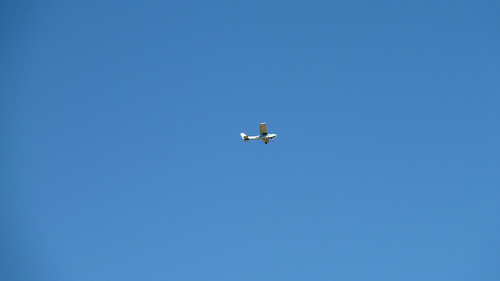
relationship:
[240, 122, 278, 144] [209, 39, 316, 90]
airplane flying under blue sky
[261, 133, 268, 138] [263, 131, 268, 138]
rectangular shape of window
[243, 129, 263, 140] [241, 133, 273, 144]
side of plane reflecting light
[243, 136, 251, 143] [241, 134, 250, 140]
dark panel on tail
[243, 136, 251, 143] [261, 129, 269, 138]
dark window under wing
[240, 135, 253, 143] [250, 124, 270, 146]
black dog against wing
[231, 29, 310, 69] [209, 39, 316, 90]
part of sky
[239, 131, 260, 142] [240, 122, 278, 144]
part of airplane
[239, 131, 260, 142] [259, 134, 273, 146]
part of wheel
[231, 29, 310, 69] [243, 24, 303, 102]
part of sky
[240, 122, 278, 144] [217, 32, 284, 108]
airplane flying in sky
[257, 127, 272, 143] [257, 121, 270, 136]
turbo engine in wing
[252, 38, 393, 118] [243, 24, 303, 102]
clear blue sky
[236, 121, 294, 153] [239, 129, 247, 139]
horizontal and vertical stabilizer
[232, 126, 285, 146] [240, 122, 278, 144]
grey color airplane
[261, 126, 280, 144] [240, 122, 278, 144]
front part of airplane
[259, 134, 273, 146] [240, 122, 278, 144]
wheel of airplane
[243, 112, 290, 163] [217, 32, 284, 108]
small plane in sky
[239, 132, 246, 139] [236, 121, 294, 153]
stabilizer of airplane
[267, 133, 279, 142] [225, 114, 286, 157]
front of airplane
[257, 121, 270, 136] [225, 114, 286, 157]
longest wing on airplane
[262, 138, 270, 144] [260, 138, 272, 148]
tiny wing on plane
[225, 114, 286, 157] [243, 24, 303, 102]
small plane in sky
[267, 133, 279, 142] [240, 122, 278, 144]
front of white airplane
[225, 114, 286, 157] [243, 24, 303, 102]
airplane in sky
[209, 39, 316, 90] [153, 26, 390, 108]
blue sky with no clouds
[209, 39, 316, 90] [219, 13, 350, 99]
blue sky with no clouds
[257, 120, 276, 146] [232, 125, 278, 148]
wings on airplane